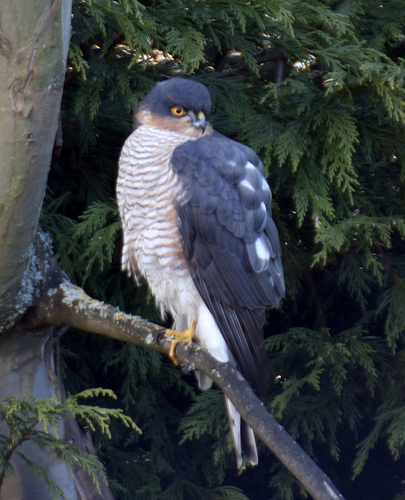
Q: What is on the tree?
A: Bark.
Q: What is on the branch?
A: Bird.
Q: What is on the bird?
A: Feathers.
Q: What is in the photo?
A: A large bird.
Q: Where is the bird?
A: On a limb.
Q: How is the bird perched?
A: On a tree limb.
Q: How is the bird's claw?
A: Wrapped around the limb.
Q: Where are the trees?
A: Behind the bird.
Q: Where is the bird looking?
A: To the right.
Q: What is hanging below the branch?
A: Bird's tail.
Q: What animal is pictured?
A: A bird.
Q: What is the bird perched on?
A: A tree branch.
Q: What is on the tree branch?
A: A bird.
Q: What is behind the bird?
A: Leaves.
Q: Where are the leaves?
A: Behind the bird.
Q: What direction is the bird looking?
A: To the right.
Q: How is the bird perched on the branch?
A: With its feet.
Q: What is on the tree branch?
A: A bird.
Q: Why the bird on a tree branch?
A: To rest.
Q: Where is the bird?
A: On a tree branch.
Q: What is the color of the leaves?
A: Green.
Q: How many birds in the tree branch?
A: One.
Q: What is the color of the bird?
A: Black, white and brown.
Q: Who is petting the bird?
A: No one.